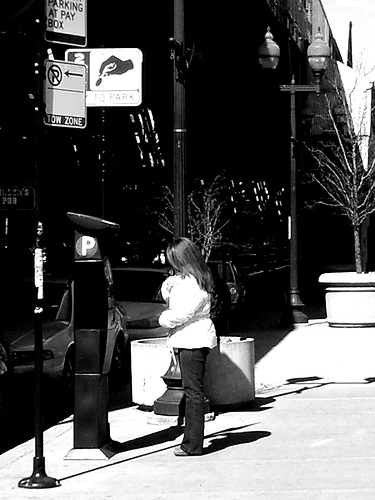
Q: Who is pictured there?
A: A woman.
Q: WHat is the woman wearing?
A: Jacket.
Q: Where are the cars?
A: Left.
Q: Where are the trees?
A: Background.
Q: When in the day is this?
A: Afternoon.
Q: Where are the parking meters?
A: Along street.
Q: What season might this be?
A: Winter.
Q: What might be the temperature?
A: Cool.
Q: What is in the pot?
A: A tree.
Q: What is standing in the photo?
A: A girl.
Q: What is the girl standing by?
A: A parking meter.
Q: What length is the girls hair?
A: Long.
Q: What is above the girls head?
A: Parking signs.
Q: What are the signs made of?
A: Metal.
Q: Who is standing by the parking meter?
A: A woman.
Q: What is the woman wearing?
A: A white coat and black trousers.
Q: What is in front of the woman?
A: A parking lot.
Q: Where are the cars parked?
A: On a curb.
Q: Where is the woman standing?
A: On the sidewalk.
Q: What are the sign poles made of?
A: Metal.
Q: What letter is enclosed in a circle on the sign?
A: P.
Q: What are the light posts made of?
A: Metal.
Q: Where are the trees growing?
A: Planters on the sidewalk.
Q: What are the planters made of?
A: Cement.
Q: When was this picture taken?
A: Daytime.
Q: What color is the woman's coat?
A: White.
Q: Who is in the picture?
A: A woman.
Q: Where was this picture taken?
A: A street corner.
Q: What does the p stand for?
A: Parking.